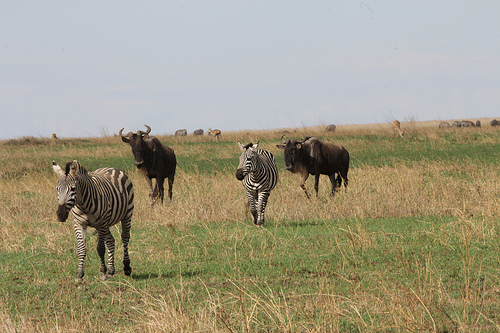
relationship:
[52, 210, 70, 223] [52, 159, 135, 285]
mouth of animal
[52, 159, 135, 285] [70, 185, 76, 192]
animal has eye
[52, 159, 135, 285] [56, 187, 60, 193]
animal has eye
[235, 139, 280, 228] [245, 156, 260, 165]
animal has eye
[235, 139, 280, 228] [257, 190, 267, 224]
animal has leg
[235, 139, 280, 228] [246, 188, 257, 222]
animal has leg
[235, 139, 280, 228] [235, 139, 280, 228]
animal has animal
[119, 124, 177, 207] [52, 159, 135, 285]
animal chasing animal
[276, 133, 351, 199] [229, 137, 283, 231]
animal chasing zebra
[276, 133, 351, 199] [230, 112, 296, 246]
animal chasing zebra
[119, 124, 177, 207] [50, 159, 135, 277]
animal chasing zebra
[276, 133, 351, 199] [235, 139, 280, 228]
animal chasing animal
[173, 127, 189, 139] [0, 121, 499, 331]
animal grazing in grass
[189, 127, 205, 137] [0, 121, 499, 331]
animal grazing in grass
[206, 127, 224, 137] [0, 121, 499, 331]
animal grazing in grass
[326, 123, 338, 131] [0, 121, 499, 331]
animal grazing in grass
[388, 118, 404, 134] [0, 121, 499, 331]
animal grazing in grass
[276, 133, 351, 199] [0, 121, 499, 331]
animal in grass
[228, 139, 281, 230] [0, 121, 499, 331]
animal in grass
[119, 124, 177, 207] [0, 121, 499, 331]
animal in grass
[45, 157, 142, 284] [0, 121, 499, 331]
animal in grass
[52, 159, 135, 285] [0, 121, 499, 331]
animal in grass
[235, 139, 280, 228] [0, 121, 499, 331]
animal in grass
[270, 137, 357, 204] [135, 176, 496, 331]
animal walking in grass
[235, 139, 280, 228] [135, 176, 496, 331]
animal walking in grass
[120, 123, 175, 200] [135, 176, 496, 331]
animal walking in grass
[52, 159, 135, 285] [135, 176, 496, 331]
animal walking in grass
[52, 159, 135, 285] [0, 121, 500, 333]
animal on area